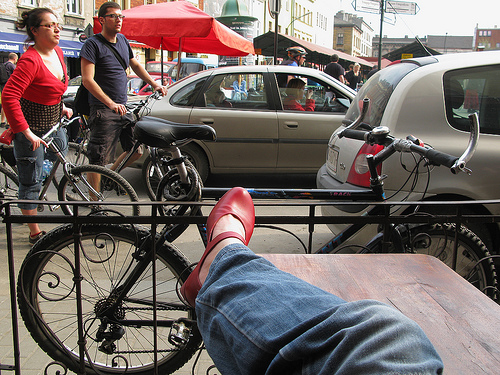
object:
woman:
[279, 77, 317, 113]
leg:
[192, 242, 445, 375]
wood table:
[252, 252, 500, 375]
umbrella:
[92, 0, 257, 89]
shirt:
[77, 32, 134, 112]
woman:
[0, 6, 74, 252]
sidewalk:
[0, 275, 224, 375]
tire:
[15, 218, 203, 375]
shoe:
[178, 186, 257, 309]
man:
[75, 1, 169, 219]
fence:
[0, 198, 500, 375]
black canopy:
[252, 32, 376, 75]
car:
[313, 48, 500, 287]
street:
[0, 144, 354, 280]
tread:
[396, 222, 499, 299]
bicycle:
[12, 96, 499, 375]